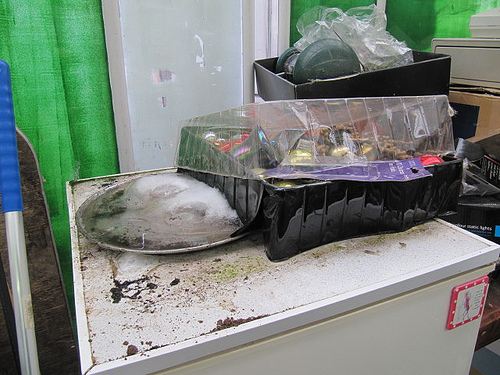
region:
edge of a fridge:
[336, 281, 370, 321]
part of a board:
[435, 276, 467, 359]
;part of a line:
[436, 268, 449, 291]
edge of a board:
[454, 283, 464, 303]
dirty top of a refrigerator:
[85, 261, 497, 352]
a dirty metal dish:
[77, 177, 239, 258]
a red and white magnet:
[449, 279, 490, 341]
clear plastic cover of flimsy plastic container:
[178, 103, 463, 169]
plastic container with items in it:
[180, 106, 465, 194]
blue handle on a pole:
[0, 55, 29, 232]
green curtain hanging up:
[17, 6, 91, 186]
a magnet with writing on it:
[457, 283, 485, 317]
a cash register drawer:
[431, 30, 498, 92]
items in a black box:
[250, 4, 444, 82]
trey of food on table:
[70, 146, 260, 264]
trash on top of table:
[178, 18, 460, 220]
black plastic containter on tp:
[229, 186, 369, 270]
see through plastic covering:
[170, 103, 384, 190]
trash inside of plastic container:
[218, 130, 348, 185]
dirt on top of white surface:
[81, 268, 191, 308]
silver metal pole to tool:
[12, 219, 42, 374]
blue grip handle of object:
[0, 60, 18, 217]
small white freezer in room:
[49, 178, 482, 374]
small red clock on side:
[445, 277, 489, 336]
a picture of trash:
[28, 3, 493, 371]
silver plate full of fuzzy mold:
[64, 157, 255, 299]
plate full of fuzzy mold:
[74, 148, 253, 280]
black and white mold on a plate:
[54, 151, 267, 304]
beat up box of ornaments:
[173, 83, 473, 249]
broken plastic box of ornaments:
[169, 90, 461, 252]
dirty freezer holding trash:
[55, 132, 492, 372]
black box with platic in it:
[263, 5, 454, 127]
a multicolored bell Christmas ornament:
[226, 114, 288, 189]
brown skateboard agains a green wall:
[1, 120, 94, 373]